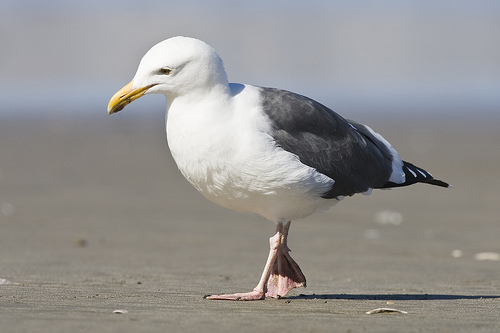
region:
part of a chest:
[166, 105, 201, 153]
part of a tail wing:
[401, 156, 446, 201]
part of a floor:
[142, 257, 194, 315]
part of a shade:
[373, 273, 408, 309]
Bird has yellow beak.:
[113, 66, 171, 149]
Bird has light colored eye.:
[158, 61, 189, 103]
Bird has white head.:
[161, 47, 218, 89]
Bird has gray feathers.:
[263, 104, 408, 187]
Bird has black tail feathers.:
[396, 147, 441, 186]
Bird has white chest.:
[192, 164, 250, 208]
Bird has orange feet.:
[258, 245, 318, 330]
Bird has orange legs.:
[258, 224, 298, 271]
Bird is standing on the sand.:
[189, 231, 295, 327]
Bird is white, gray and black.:
[103, 43, 375, 253]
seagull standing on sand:
[83, 28, 451, 308]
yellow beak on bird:
[100, 78, 154, 128]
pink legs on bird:
[210, 224, 308, 308]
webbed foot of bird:
[260, 248, 312, 300]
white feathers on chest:
[167, 120, 244, 187]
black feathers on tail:
[402, 163, 454, 193]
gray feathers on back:
[268, 93, 321, 128]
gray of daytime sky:
[320, 8, 417, 55]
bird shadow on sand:
[335, 283, 465, 306]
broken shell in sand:
[356, 303, 412, 320]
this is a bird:
[95, 61, 404, 278]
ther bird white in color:
[176, 126, 241, 183]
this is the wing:
[276, 91, 345, 169]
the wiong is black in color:
[288, 106, 321, 140]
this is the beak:
[92, 84, 147, 114]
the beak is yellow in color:
[106, 86, 136, 110]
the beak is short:
[100, 76, 149, 118]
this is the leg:
[209, 225, 316, 303]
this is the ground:
[327, 282, 427, 321]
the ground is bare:
[329, 268, 431, 330]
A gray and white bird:
[100, 40, 466, 310]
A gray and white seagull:
[98, 31, 456, 306]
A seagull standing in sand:
[96, 40, 457, 315]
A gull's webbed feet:
[196, 230, 326, 315]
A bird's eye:
[147, 45, 187, 91]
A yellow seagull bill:
[97, 76, 155, 121]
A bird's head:
[125, 27, 246, 108]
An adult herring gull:
[90, 40, 466, 307]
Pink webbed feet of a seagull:
[200, 230, 332, 315]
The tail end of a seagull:
[340, 98, 467, 216]